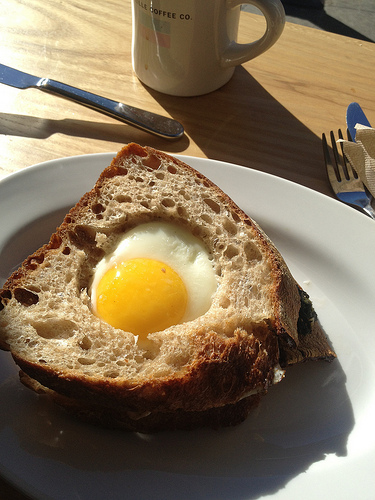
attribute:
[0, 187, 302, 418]
sandwich — breakfast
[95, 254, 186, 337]
yolk — unbroken, yellow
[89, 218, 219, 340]
egg — small, round, white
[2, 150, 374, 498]
plate — white, large, ceramic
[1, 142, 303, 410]
sandwich — egg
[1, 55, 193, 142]
knife — silver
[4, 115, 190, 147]
shadow — black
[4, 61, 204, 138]
knife — one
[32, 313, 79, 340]
hole — one, small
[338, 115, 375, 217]
napkin — white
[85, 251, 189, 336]
yolk — Yellow , egg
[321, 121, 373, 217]
fork — Silver 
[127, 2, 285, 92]
cup — coffee 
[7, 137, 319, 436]
bread — some, sliced, one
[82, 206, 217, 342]
egg — one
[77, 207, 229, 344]
egg — cooked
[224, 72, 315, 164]
table — light brown, wooden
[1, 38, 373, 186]
table — one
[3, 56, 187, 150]
knife — one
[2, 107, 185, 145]
shadow — one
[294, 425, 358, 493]
plate — white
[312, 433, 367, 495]
plate — ceramic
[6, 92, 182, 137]
knife — silver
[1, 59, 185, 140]
knife — silver, long, metal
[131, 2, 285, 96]
mug — white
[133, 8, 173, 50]
print — red, pink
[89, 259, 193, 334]
yoke — small, round, yellow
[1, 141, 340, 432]
bread — large, brown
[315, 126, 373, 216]
fork — metal, long, silver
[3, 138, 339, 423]
crust — brown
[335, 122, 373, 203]
paper napkin — small, white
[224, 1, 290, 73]
handle — curved, white, ceramic